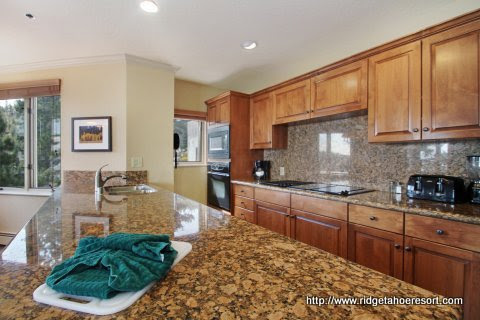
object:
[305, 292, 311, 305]
letter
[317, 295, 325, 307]
letter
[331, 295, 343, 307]
letter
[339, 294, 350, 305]
letter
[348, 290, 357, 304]
letter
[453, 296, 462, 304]
letter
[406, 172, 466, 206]
toaster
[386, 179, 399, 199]
shaker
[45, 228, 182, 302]
towel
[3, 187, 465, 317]
table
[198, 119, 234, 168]
microwave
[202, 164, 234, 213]
oven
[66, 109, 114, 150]
picture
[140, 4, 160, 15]
light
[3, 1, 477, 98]
ceiling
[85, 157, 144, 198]
faucet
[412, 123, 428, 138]
knobs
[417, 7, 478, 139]
cabinet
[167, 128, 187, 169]
phone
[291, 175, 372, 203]
stove top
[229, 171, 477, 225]
counter top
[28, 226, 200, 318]
board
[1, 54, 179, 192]
wall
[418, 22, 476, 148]
cabinets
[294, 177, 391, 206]
sink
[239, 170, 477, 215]
counter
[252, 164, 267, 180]
pot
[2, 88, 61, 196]
windows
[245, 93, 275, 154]
door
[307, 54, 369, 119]
door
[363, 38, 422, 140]
door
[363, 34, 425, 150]
cabinet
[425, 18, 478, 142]
door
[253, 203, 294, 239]
cabinet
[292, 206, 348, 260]
door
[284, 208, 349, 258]
cabinet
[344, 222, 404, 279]
door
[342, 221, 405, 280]
cabinet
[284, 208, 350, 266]
door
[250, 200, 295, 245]
door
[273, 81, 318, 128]
door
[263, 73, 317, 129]
cabinet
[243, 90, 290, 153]
cabinet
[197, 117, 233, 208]
stove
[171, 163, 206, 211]
wall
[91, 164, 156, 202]
sink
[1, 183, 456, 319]
countertops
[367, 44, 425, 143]
door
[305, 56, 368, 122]
cabinet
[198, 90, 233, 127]
door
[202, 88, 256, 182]
cabinet